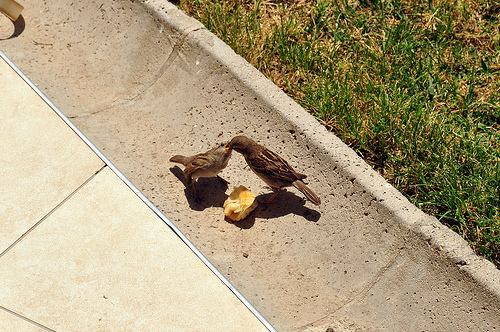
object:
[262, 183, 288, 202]
legs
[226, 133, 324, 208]
fird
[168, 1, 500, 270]
field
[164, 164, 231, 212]
shadow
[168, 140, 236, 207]
bird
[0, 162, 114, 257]
crack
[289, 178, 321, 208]
tail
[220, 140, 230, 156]
head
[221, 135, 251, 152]
head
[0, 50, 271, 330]
tile ground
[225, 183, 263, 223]
food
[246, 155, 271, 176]
feather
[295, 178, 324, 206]
feather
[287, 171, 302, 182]
feather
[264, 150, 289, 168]
feather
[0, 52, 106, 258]
concreter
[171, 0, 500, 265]
grass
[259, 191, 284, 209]
talons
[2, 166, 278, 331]
tile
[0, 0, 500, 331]
ground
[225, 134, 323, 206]
bird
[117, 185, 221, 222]
bird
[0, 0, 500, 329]
curb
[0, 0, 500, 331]
sidewalk